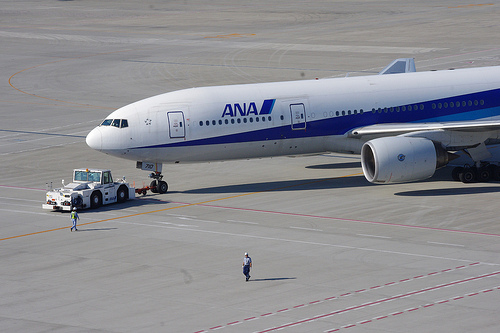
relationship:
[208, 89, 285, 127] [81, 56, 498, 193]
logo on plane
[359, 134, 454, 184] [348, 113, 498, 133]
engine under wing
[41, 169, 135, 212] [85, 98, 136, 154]
truck under nose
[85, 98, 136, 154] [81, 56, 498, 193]
nose of plane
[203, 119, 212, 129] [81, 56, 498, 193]
window on plane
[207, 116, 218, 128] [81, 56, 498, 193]
window on plane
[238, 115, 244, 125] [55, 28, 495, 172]
window on plane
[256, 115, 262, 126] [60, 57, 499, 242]
window on plane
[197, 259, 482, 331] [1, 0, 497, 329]
line on pavement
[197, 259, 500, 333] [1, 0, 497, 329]
line on pavement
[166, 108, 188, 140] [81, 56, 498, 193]
window on plane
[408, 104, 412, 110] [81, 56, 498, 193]
window on plane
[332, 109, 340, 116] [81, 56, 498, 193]
window on plane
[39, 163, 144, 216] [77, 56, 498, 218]
truck attached to plane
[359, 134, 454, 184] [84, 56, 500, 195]
engine on airplane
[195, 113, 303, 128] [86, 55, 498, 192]
windows on fuselage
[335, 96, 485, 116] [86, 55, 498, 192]
windows on fuselage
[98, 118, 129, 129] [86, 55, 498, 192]
windows on fuselage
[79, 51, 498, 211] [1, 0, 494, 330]
airplane on tarmac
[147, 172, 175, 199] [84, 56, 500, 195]
landing gear on airplane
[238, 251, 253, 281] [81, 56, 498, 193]
man walking from plane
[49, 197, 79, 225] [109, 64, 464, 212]
man walking to plane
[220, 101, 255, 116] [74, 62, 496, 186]
airline name on plane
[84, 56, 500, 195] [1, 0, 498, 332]
airplane on runway